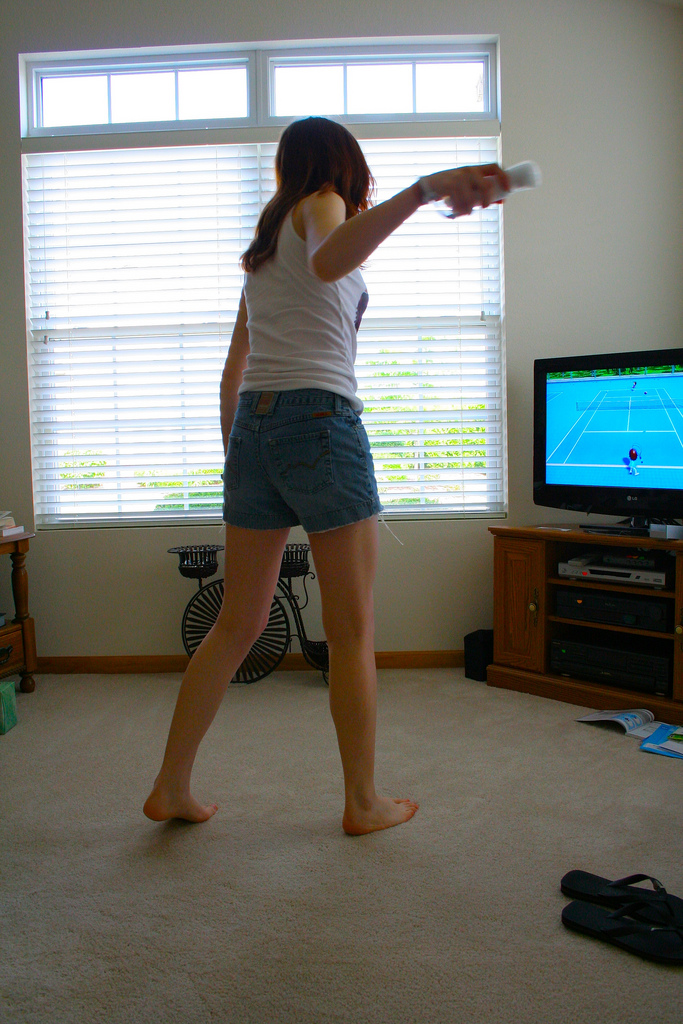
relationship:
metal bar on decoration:
[204, 587, 217, 606] [156, 527, 324, 685]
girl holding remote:
[143, 117, 511, 837] [407, 159, 544, 223]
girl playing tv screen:
[143, 117, 511, 837] [545, 365, 682, 492]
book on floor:
[574, 698, 679, 743] [9, 664, 680, 1017]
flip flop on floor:
[560, 894, 679, 970] [9, 664, 680, 1017]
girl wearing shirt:
[143, 117, 511, 837] [233, 207, 372, 405]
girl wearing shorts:
[143, 117, 511, 837] [213, 380, 384, 538]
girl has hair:
[143, 117, 511, 837] [237, 114, 381, 271]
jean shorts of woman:
[217, 381, 390, 537] [128, 108, 490, 843]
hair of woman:
[237, 114, 381, 271] [128, 108, 490, 843]